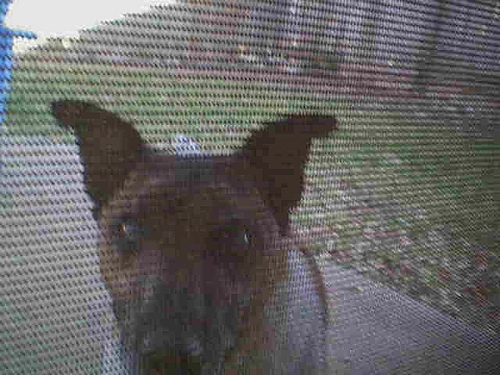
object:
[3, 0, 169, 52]
light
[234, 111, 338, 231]
ear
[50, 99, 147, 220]
ear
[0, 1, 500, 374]
pattern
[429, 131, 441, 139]
leaves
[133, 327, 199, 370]
nose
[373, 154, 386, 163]
leaves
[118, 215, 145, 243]
eye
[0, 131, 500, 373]
ground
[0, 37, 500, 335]
grass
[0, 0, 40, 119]
object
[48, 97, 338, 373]
dog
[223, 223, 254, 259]
eye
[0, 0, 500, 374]
fence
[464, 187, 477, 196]
leaves